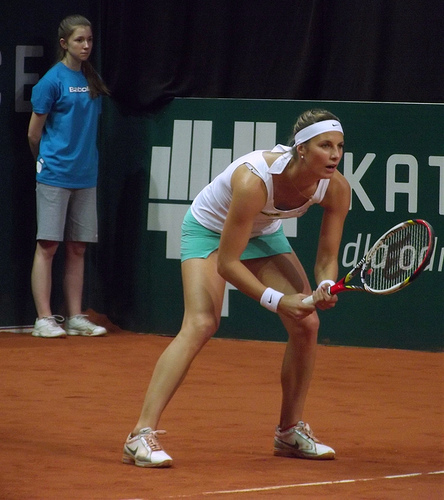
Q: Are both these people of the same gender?
A: Yes, all the people are female.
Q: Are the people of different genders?
A: No, all the people are female.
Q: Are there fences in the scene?
A: No, there are no fences.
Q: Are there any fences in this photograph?
A: No, there are no fences.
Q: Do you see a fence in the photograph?
A: No, there are no fences.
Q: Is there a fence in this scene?
A: No, there are no fences.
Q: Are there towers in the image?
A: No, there are no towers.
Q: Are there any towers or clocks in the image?
A: No, there are no towers or clocks.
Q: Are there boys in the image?
A: No, there are no boys.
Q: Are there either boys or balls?
A: No, there are no boys or balls.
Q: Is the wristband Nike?
A: Yes, the wristband is nike.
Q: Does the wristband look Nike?
A: Yes, the wristband is nike.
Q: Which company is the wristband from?
A: The wristband is from nike.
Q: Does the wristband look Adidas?
A: No, the wristband is nike.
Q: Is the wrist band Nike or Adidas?
A: The wrist band is nike.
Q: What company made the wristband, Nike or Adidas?
A: The wristband was made nike.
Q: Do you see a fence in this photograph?
A: No, there are no fences.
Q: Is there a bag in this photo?
A: No, there are no bags.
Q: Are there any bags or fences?
A: No, there are no bags or fences.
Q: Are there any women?
A: Yes, there is a woman.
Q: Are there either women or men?
A: Yes, there is a woman.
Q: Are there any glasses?
A: No, there are no glasses.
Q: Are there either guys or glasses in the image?
A: No, there are no glasses or guys.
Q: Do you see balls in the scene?
A: No, there are no balls.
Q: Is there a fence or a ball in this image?
A: No, there are no balls or fences.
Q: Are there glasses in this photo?
A: No, there are no glasses.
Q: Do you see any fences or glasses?
A: No, there are no glasses or fences.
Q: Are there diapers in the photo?
A: No, there are no diapers.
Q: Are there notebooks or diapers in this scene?
A: No, there are no diapers or notebooks.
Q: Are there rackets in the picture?
A: Yes, there is a racket.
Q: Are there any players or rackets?
A: Yes, there is a racket.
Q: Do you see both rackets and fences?
A: No, there is a racket but no fences.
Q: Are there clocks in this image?
A: No, there are no clocks.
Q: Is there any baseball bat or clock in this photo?
A: No, there are no clocks or baseball bats.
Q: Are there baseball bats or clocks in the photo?
A: No, there are no clocks or baseball bats.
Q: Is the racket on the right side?
A: Yes, the racket is on the right of the image.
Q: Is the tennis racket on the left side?
A: No, the tennis racket is on the right of the image.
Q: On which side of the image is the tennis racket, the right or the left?
A: The tennis racket is on the right of the image.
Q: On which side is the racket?
A: The racket is on the right of the image.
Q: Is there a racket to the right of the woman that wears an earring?
A: Yes, there is a racket to the right of the woman.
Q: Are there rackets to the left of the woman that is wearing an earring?
A: No, the racket is to the right of the woman.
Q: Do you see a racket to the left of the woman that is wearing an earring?
A: No, the racket is to the right of the woman.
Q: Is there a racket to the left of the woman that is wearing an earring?
A: No, the racket is to the right of the woman.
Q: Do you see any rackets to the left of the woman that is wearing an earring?
A: No, the racket is to the right of the woman.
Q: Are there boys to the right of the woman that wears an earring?
A: No, there is a racket to the right of the woman.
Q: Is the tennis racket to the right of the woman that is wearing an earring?
A: Yes, the tennis racket is to the right of the woman.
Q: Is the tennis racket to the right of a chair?
A: No, the tennis racket is to the right of the woman.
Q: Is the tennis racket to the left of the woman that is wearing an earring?
A: No, the tennis racket is to the right of the woman.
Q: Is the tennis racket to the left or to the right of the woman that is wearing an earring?
A: The tennis racket is to the right of the woman.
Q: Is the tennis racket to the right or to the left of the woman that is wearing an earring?
A: The tennis racket is to the right of the woman.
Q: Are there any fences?
A: No, there are no fences.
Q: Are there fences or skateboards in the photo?
A: No, there are no fences or skateboards.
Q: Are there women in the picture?
A: Yes, there is a woman.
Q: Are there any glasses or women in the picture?
A: Yes, there is a woman.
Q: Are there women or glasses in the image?
A: Yes, there is a woman.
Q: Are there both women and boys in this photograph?
A: No, there is a woman but no boys.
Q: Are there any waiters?
A: No, there are no waiters.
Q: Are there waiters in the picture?
A: No, there are no waiters.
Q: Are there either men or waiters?
A: No, there are no waiters or men.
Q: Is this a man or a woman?
A: This is a woman.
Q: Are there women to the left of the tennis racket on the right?
A: Yes, there is a woman to the left of the tennis racket.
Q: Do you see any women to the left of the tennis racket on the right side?
A: Yes, there is a woman to the left of the tennis racket.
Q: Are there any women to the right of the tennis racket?
A: No, the woman is to the left of the tennis racket.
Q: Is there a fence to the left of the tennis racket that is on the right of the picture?
A: No, there is a woman to the left of the racket.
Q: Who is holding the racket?
A: The woman is holding the racket.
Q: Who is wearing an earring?
A: The woman is wearing an earring.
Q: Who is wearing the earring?
A: The woman is wearing an earring.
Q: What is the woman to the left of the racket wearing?
A: The woman is wearing an earring.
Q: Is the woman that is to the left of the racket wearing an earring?
A: Yes, the woman is wearing an earring.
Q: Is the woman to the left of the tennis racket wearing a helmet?
A: No, the woman is wearing an earring.